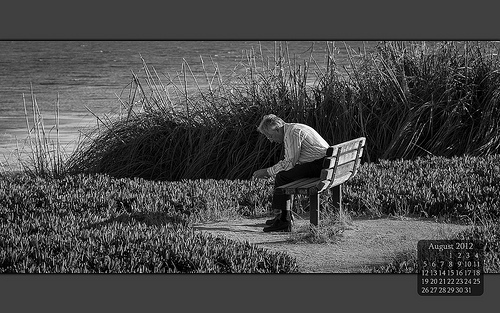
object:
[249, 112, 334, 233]
man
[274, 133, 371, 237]
park bench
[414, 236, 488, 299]
calender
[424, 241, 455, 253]
august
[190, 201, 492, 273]
platform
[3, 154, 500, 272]
grass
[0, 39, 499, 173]
water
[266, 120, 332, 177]
shirt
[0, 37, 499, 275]
border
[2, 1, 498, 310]
picture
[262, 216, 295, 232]
shoes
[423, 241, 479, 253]
august 2012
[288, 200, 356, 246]
weeds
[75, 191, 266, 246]
shadow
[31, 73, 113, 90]
ripples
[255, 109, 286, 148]
head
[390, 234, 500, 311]
corner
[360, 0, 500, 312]
right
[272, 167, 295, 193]
knees